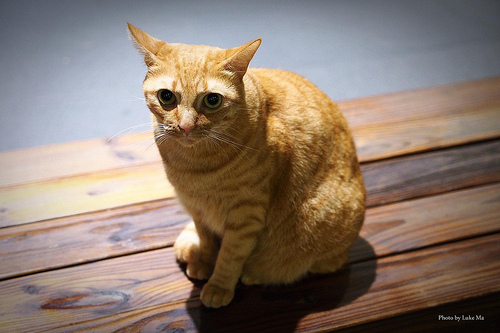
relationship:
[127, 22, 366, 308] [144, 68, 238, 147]
cat has face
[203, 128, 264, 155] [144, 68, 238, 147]
whisker on side of face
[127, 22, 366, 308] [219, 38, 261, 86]
cat has ear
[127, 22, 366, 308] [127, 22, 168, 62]
cat has ear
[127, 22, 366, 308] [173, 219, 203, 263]
cat has tail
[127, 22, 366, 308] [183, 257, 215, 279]
cat has paw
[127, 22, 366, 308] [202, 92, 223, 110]
cat has eye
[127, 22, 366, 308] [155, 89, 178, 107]
cat has eye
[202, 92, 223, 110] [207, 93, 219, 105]
eye has pupil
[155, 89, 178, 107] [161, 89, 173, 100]
eye has pupil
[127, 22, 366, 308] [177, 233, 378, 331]
cat has shadow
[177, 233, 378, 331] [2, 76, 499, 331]
shadow on top of bench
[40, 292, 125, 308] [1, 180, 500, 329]
knot in middle of wood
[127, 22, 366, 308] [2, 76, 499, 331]
cat on top of bench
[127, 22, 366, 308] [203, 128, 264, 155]
cat has whisker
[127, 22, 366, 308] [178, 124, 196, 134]
cat has nose